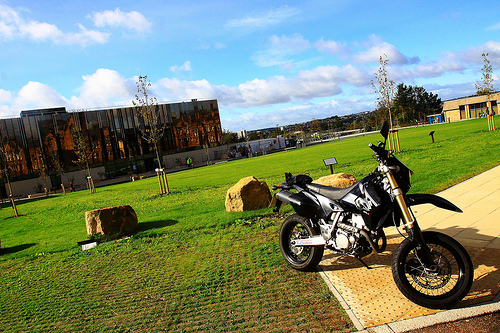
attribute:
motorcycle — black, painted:
[270, 119, 484, 310]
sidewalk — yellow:
[289, 161, 499, 332]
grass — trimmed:
[0, 116, 500, 332]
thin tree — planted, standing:
[132, 75, 181, 195]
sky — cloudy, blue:
[5, 0, 499, 132]